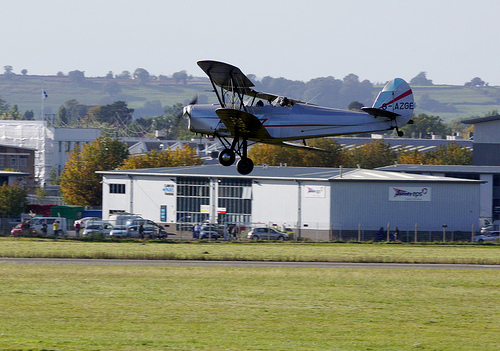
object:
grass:
[31, 276, 218, 346]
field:
[7, 250, 488, 348]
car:
[247, 226, 290, 240]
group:
[5, 212, 288, 239]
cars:
[10, 209, 300, 247]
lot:
[2, 210, 324, 250]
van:
[11, 213, 63, 239]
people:
[51, 220, 60, 238]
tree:
[61, 135, 126, 210]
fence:
[315, 218, 488, 245]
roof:
[100, 159, 483, 192]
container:
[24, 200, 84, 230]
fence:
[6, 219, 490, 243]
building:
[97, 161, 479, 246]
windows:
[161, 171, 255, 220]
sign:
[374, 180, 444, 212]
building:
[99, 160, 469, 245]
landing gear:
[217, 142, 253, 174]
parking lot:
[15, 219, 296, 243]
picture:
[2, 1, 497, 344]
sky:
[67, 3, 457, 76]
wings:
[196, 59, 272, 143]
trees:
[53, 71, 229, 116]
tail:
[349, 77, 416, 134]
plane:
[175, 60, 419, 177]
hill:
[34, 55, 443, 134]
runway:
[48, 242, 478, 278]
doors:
[174, 175, 254, 238]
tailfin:
[347, 68, 419, 141]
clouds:
[75, 3, 431, 98]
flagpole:
[40, 83, 48, 115]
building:
[2, 118, 104, 207]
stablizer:
[366, 77, 416, 129]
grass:
[35, 237, 443, 261]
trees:
[64, 131, 128, 215]